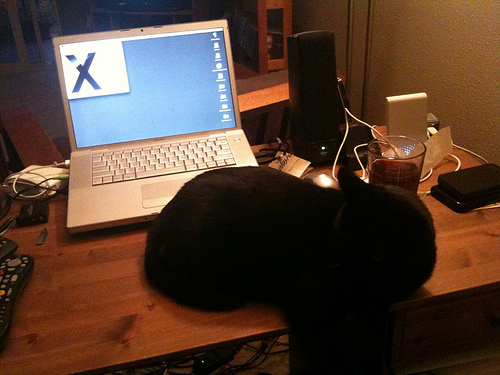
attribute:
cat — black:
[138, 159, 443, 325]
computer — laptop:
[54, 32, 242, 158]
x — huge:
[65, 48, 106, 100]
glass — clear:
[365, 132, 428, 199]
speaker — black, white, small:
[154, 25, 164, 29]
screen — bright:
[130, 53, 185, 83]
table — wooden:
[461, 225, 496, 271]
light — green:
[316, 144, 330, 152]